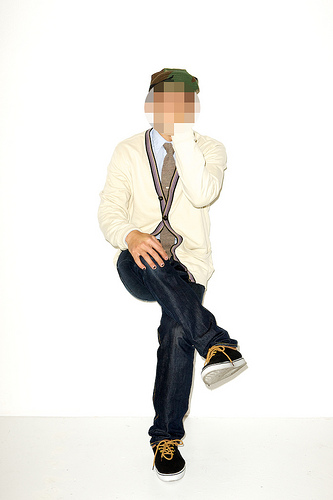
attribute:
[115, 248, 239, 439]
trouser — edge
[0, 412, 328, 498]
floor — part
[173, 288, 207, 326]
leg — pant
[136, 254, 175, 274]
nails — painted, dark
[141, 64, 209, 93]
hat — green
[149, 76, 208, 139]
face — blurred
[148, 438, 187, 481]
black/white shoe — black, white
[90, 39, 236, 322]
person — blurred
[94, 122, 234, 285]
sweater — brown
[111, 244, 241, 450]
jeans — blue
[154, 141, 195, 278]
tie — brown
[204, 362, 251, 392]
sneaker bottoms — white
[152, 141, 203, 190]
tie — brown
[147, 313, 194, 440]
pant leg — jean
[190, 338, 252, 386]
shoe — black, white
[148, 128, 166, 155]
collar — blue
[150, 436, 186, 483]
shoe — black, white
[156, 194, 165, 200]
button — black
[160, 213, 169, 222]
button — black